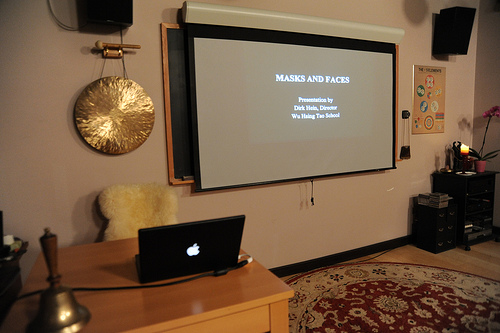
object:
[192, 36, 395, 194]
projector screen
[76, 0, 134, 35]
speaker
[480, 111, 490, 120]
flower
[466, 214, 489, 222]
book shelf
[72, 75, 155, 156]
golden instrument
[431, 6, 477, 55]
speaker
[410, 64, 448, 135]
board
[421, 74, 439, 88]
sticker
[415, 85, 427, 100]
sticker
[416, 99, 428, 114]
sticker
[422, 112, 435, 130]
sticker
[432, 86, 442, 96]
sticker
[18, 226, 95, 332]
bell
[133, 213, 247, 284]
laptop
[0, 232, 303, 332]
desk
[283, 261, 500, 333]
rug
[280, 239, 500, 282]
floor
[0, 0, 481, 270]
wall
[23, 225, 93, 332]
candle stick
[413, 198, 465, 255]
filing cabinet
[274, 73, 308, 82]
words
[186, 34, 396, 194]
screeb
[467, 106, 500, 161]
pink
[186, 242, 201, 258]
apple